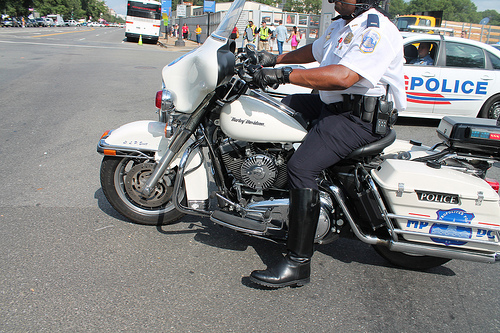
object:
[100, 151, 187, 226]
front wheel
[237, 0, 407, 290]
officer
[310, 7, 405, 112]
shirt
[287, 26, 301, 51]
woman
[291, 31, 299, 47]
top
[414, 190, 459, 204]
lettering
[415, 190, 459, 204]
background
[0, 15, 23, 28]
cars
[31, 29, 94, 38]
line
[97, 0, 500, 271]
motorcycle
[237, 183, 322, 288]
boot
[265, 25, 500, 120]
car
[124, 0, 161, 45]
bus